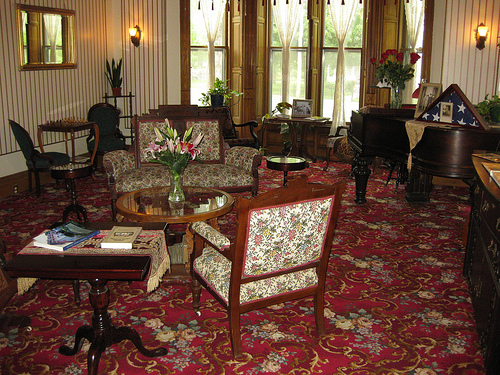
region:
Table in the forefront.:
[8, 210, 177, 374]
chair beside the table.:
[186, 175, 348, 357]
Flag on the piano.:
[410, 78, 490, 134]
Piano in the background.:
[336, 94, 497, 207]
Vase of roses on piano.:
[367, 37, 419, 109]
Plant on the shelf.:
[102, 55, 129, 95]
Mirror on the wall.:
[14, 25, 85, 75]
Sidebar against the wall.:
[461, 148, 497, 373]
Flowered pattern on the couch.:
[97, 112, 263, 226]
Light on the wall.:
[467, 16, 490, 55]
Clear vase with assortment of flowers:
[141, 117, 206, 202]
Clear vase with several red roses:
[368, 47, 419, 110]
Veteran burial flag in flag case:
[415, 82, 488, 134]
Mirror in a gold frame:
[14, 3, 79, 71]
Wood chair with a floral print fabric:
[188, 173, 345, 358]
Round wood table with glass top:
[114, 184, 235, 289]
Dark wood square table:
[2, 220, 167, 374]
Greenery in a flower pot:
[197, 76, 244, 108]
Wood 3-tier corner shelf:
[100, 90, 136, 147]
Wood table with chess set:
[35, 116, 100, 188]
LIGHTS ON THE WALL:
[476, 22, 484, 44]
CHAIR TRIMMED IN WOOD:
[258, 193, 269, 203]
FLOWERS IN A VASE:
[162, 134, 186, 170]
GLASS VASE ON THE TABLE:
[166, 177, 177, 199]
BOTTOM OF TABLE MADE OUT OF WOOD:
[91, 308, 112, 343]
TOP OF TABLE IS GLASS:
[200, 190, 212, 210]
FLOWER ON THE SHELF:
[105, 59, 122, 91]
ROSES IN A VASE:
[372, 48, 413, 83]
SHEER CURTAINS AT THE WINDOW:
[341, 16, 343, 107]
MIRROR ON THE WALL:
[21, 8, 79, 67]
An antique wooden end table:
[3, 220, 168, 374]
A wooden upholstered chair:
[189, 175, 346, 361]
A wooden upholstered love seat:
[104, 104, 262, 221]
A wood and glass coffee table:
[112, 183, 236, 273]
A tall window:
[189, 1, 227, 106]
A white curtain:
[271, 1, 302, 116]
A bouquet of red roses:
[369, 47, 421, 110]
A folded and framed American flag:
[414, 83, 489, 128]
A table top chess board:
[40, 114, 94, 131]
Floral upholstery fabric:
[241, 196, 334, 278]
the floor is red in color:
[331, 195, 429, 335]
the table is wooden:
[58, 259, 132, 364]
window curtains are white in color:
[326, 12, 348, 126]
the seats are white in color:
[203, 156, 259, 182]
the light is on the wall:
[118, 22, 150, 44]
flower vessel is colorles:
[163, 174, 200, 227]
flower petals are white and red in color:
[148, 132, 208, 169]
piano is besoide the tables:
[361, 107, 484, 193]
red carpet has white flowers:
[365, 239, 445, 326]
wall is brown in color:
[243, 37, 268, 115]